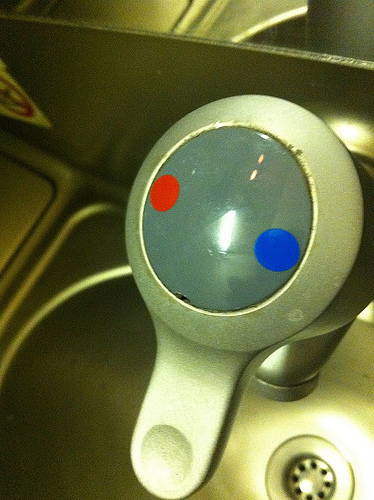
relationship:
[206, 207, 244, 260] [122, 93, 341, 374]
light reflecting on handle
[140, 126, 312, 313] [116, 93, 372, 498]
circular insert on faucet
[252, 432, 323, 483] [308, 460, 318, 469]
drain has hole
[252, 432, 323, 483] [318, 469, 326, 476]
drain has hole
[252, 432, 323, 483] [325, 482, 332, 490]
drain has hole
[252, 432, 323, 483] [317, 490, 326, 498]
drain has hole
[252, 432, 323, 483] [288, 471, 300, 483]
drain has hole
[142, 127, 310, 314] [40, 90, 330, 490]
top center of faucet